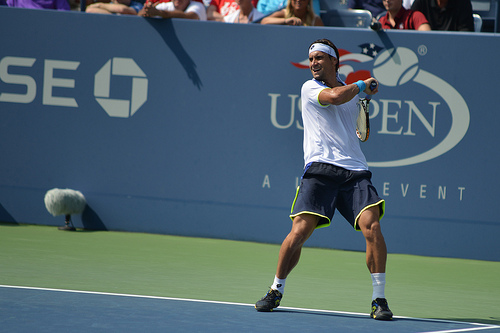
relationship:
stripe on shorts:
[290, 188, 389, 230] [284, 163, 387, 230]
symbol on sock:
[273, 282, 284, 291] [267, 278, 287, 296]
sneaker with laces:
[256, 287, 284, 314] [262, 289, 282, 308]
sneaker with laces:
[365, 297, 394, 321] [374, 297, 387, 309]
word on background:
[3, 52, 150, 117] [5, 3, 498, 232]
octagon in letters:
[89, 53, 153, 116] [0, 53, 88, 107]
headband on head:
[308, 42, 340, 59] [303, 35, 344, 83]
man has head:
[256, 37, 395, 320] [303, 35, 344, 83]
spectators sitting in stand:
[5, 0, 498, 36] [3, 2, 498, 237]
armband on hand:
[348, 78, 370, 97] [362, 78, 381, 95]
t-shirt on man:
[291, 75, 374, 171] [256, 37, 395, 320]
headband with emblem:
[308, 42, 340, 59] [307, 45, 320, 53]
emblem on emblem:
[307, 45, 320, 53] [307, 43, 322, 53]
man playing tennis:
[256, 37, 395, 320] [6, 0, 499, 323]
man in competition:
[242, 23, 415, 319] [6, 0, 499, 326]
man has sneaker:
[242, 23, 415, 319] [256, 287, 284, 314]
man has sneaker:
[242, 23, 415, 319] [365, 297, 394, 321]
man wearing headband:
[242, 23, 415, 319] [308, 42, 340, 59]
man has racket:
[242, 23, 415, 319] [354, 78, 379, 141]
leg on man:
[271, 216, 320, 285] [242, 23, 415, 319]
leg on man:
[358, 207, 386, 272] [242, 23, 415, 319]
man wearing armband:
[242, 23, 415, 319] [348, 78, 370, 97]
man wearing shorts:
[242, 23, 415, 319] [284, 163, 387, 230]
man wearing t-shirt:
[242, 23, 415, 319] [299, 77, 372, 172]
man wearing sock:
[242, 23, 415, 319] [267, 278, 287, 296]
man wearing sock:
[242, 23, 415, 319] [370, 270, 388, 302]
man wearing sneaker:
[256, 37, 395, 320] [256, 287, 284, 314]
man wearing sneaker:
[256, 37, 395, 320] [365, 297, 394, 321]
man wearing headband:
[256, 37, 395, 320] [308, 42, 340, 59]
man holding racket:
[256, 37, 395, 320] [354, 78, 379, 141]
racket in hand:
[354, 78, 379, 141] [362, 78, 381, 95]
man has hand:
[256, 37, 395, 320] [362, 78, 381, 95]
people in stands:
[5, 0, 498, 36] [3, 2, 498, 237]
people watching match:
[5, 0, 498, 36] [6, 0, 499, 323]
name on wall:
[259, 41, 491, 210] [1, 3, 498, 262]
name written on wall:
[259, 41, 491, 210] [1, 3, 498, 262]